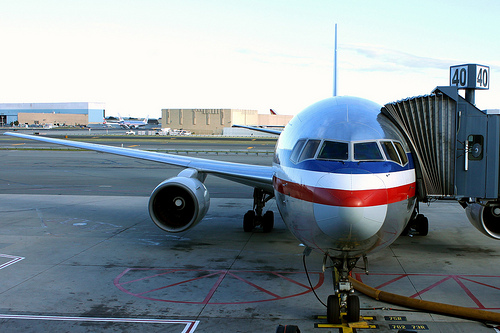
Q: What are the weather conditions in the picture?
A: It is cloudy.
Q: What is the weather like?
A: It is cloudy.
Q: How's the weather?
A: It is cloudy.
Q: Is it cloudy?
A: Yes, it is cloudy.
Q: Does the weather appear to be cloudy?
A: Yes, it is cloudy.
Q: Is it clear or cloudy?
A: It is cloudy.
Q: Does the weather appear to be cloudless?
A: No, it is cloudy.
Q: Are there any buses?
A: No, there are no buses.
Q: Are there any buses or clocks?
A: No, there are no buses or clocks.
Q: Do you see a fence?
A: No, there are no fences.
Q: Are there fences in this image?
A: No, there are no fences.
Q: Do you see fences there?
A: No, there are no fences.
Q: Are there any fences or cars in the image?
A: No, there are no fences or cars.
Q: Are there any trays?
A: No, there are no trays.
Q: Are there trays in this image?
A: No, there are no trays.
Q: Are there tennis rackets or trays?
A: No, there are no trays or tennis rackets.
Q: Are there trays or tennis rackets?
A: No, there are no trays or tennis rackets.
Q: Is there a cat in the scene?
A: No, there are no cats.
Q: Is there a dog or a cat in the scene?
A: No, there are no cats or dogs.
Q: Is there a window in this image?
A: Yes, there are windows.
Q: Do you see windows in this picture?
A: Yes, there are windows.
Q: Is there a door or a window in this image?
A: Yes, there are windows.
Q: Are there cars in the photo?
A: No, there are no cars.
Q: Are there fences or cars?
A: No, there are no cars or fences.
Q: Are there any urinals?
A: No, there are no urinals.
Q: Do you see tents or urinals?
A: No, there are no urinals or tents.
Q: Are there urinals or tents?
A: No, there are no urinals or tents.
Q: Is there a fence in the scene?
A: No, there are no fences.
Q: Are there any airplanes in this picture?
A: Yes, there is an airplane.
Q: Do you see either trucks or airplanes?
A: Yes, there is an airplane.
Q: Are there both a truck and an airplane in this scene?
A: No, there is an airplane but no trucks.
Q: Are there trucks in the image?
A: No, there are no trucks.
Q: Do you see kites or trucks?
A: No, there are no trucks or kites.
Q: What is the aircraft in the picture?
A: The aircraft is an airplane.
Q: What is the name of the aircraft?
A: The aircraft is an airplane.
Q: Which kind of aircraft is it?
A: The aircraft is an airplane.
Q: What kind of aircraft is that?
A: This is an airplane.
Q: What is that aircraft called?
A: This is an airplane.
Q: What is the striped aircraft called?
A: The aircraft is an airplane.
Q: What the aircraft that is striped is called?
A: The aircraft is an airplane.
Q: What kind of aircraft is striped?
A: The aircraft is an airplane.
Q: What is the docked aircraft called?
A: The aircraft is an airplane.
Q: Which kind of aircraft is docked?
A: The aircraft is an airplane.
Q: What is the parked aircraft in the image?
A: The aircraft is an airplane.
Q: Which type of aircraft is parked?
A: The aircraft is an airplane.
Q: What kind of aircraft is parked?
A: The aircraft is an airplane.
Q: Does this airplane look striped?
A: Yes, the airplane is striped.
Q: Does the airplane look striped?
A: Yes, the airplane is striped.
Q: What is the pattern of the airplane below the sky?
A: The airplane is striped.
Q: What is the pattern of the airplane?
A: The airplane is striped.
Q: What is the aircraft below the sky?
A: The aircraft is an airplane.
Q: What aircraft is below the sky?
A: The aircraft is an airplane.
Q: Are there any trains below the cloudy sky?
A: No, there is an airplane below the sky.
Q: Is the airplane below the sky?
A: Yes, the airplane is below the sky.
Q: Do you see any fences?
A: No, there are no fences.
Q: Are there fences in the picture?
A: No, there are no fences.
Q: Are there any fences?
A: No, there are no fences.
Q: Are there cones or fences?
A: No, there are no fences or cones.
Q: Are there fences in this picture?
A: No, there are no fences.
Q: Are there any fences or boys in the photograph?
A: No, there are no fences or boys.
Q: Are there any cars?
A: No, there are no cars.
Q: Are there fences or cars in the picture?
A: No, there are no cars or fences.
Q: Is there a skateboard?
A: No, there are no skateboards.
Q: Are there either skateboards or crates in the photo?
A: No, there are no skateboards or crates.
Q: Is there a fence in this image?
A: No, there are no fences.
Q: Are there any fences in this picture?
A: No, there are no fences.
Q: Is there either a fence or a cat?
A: No, there are no fences or cats.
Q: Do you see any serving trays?
A: No, there are no serving trays.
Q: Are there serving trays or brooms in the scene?
A: No, there are no serving trays or brooms.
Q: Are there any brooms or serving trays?
A: No, there are no serving trays or brooms.